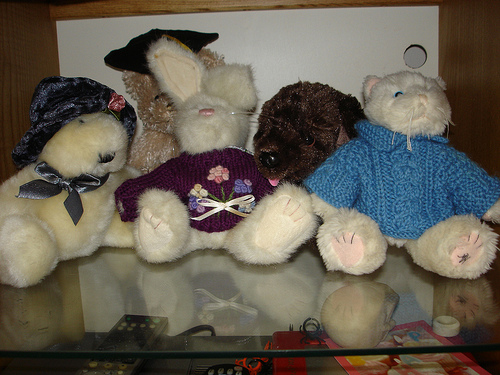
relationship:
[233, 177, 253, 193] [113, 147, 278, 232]
flower on sweater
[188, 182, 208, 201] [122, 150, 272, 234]
flower on sweater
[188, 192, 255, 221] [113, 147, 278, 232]
bow on sweater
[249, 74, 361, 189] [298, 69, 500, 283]
face of animal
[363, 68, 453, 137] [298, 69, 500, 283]
face of animal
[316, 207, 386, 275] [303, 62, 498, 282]
leg of toy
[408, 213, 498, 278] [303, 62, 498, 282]
leg of toy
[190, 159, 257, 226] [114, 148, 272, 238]
design on shirt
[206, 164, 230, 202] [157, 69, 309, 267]
design on doll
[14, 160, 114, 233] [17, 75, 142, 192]
tie to head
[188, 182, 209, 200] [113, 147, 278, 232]
flower knitted on sweater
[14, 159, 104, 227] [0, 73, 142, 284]
bow on bear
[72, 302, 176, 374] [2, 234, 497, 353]
remote control under glass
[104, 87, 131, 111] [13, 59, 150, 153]
rose on hat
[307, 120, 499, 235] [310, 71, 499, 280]
sweater on cat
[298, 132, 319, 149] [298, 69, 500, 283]
brown eye on animal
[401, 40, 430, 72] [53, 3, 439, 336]
hole in board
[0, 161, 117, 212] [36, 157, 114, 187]
bow on neck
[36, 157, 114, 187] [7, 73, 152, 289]
neck of bear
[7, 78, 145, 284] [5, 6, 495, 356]
animal sitting on shelf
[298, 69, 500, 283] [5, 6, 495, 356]
animal sitting on shelf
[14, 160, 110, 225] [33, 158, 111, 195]
tie on neck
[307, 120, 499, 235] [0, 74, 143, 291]
sweater on cat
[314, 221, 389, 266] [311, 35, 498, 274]
foot of stuffed cat